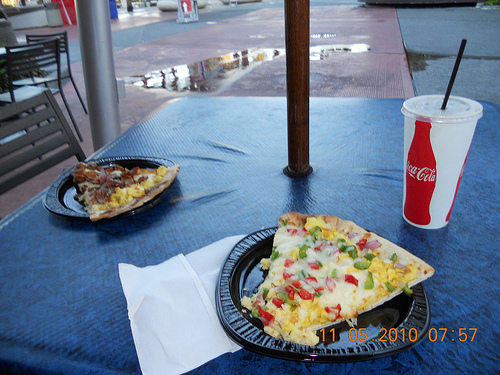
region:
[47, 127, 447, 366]
two slices of pizza are on plates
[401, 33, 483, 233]
a drink sits on the table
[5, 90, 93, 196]
the back of a chair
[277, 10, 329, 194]
a pole is in the middle of the table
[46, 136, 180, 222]
the plate is black in color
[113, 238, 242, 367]
a napkin is on the table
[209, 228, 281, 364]
the plate is on top of the napkin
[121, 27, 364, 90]
a puddle of water is on the ground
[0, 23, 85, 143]
more chairs are in the background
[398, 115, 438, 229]
the cup displays a Coca~Cola logo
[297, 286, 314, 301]
red tomato on pizza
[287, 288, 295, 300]
red tomato on pizza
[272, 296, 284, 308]
red tomato on pizza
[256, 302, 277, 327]
red tomato on pizza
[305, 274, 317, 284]
red tomato on pizza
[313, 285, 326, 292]
red tomato on pizza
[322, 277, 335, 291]
red tomato on pizza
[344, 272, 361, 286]
red tomato on pizza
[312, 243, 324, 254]
red tomato on pizza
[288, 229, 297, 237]
red tomato on pizza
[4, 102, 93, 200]
grey metal chair with slats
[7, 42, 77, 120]
grey metal chair with slats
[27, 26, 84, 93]
grey metal chair with slats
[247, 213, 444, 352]
slice of cheesy pizza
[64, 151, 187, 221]
slice of cheesy pizza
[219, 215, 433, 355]
pizza on a black plastic plate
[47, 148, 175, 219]
pizza slice on black plastic plate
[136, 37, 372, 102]
puddle of water on ground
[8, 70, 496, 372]
blue and black plastic tablecloth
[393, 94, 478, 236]
white and red disposable cup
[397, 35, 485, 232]
a plastic drinking cup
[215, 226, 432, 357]
a black plastic dinner plate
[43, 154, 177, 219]
a black plastic dinner plate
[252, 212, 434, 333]
a large slice of pizza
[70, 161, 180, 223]
a large slice of pizza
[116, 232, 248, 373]
a white paper napkin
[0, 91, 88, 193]
a black patio chair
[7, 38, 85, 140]
a black patio chair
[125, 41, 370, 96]
a small puddle of water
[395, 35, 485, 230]
cup of coca cola on a table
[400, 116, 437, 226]
red coca cola bottle graphic on a cup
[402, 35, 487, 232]
black straw in a coca cola cup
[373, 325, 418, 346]
orange print reading 2010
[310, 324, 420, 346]
orange date print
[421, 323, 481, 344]
orange time stamp print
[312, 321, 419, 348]
date stamp reading 11 05 2010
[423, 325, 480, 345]
time stamp reading 07: 57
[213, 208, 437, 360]
colorful slice of pizza on a black plate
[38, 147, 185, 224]
slice of pizza on a plate